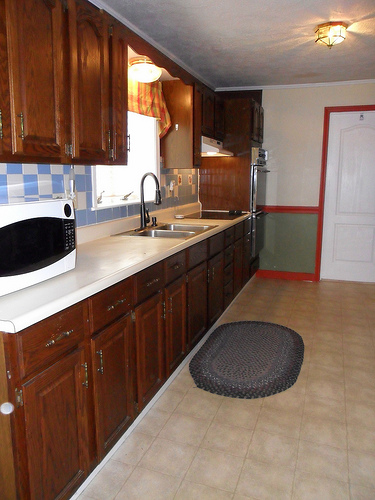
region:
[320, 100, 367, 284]
the door is white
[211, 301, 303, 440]
rug on the floor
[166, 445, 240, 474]
the floor is tile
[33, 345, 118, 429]
the cabinets are wood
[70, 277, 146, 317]
the drawers are wood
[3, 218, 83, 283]
the microwave is white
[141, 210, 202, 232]
the sink is steel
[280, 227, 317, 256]
the wall is green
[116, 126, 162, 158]
the window is bright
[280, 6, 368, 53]
light on the ceiling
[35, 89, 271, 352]
the cabinets are wooden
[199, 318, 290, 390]
A lone washing mat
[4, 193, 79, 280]
the microwave is white and black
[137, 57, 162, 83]
the light is on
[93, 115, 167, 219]
light shines through the window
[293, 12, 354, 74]
the light is on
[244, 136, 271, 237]
the fridge is silver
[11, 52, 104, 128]
the cabinet is brown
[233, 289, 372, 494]
the kitchen is tiled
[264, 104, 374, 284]
Reddish brown colored stain wood trim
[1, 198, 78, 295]
White and black microwave oven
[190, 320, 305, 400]
Gray tone oval rug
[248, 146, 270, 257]
Stainless steal double oven built in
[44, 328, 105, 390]
Antique brass drawer pulls and door hardware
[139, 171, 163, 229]
Black kitchen faucet with single handle control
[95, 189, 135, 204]
Crank handle controls for windows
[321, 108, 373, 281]
Double panel white door with centered hook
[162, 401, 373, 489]
Tiled look linoleum kitchen floor in tan marble pattern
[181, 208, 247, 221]
Flat surface black stove top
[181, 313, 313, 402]
Mat on the floor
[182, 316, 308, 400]
Mat is on the floor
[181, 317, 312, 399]
Mat on the kitchen floor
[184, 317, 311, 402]
Mat is on the kitchen floor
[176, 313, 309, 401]
Gray mat on the floor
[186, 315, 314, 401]
Gray mat is on the floor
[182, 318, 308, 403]
Gray mat on the kitchen floor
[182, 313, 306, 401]
Gray mat is on the kitchen floor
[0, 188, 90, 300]
Microwave is on the counter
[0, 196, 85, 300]
White and black microwave on the counter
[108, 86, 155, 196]
a window in the kitchen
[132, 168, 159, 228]
the faucet of the sink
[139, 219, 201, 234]
the sink in the kichen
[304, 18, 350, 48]
a light on the ceiling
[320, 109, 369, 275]
a white door in the kitchen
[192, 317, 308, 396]
a blue rug on the floor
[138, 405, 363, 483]
white tile on the floor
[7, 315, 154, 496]
wooden cabinets